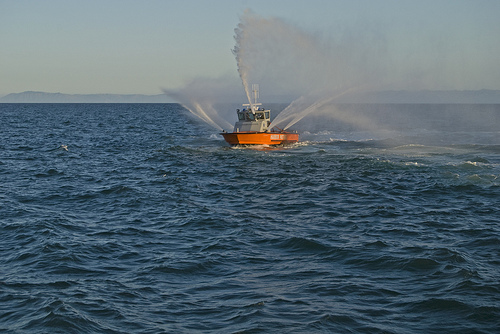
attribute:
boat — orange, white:
[218, 101, 300, 154]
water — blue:
[4, 106, 494, 284]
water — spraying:
[225, 19, 272, 105]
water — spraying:
[274, 91, 355, 129]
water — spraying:
[163, 85, 227, 135]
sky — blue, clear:
[6, 5, 499, 66]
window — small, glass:
[237, 112, 246, 121]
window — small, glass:
[245, 112, 256, 121]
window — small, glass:
[257, 112, 266, 121]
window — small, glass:
[264, 112, 269, 121]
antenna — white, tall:
[243, 80, 266, 108]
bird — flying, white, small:
[58, 139, 74, 154]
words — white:
[264, 133, 291, 142]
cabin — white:
[234, 114, 275, 135]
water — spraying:
[275, 99, 321, 112]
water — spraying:
[189, 94, 227, 124]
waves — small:
[91, 172, 151, 200]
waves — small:
[368, 142, 471, 172]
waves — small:
[27, 273, 109, 321]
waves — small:
[132, 106, 179, 127]